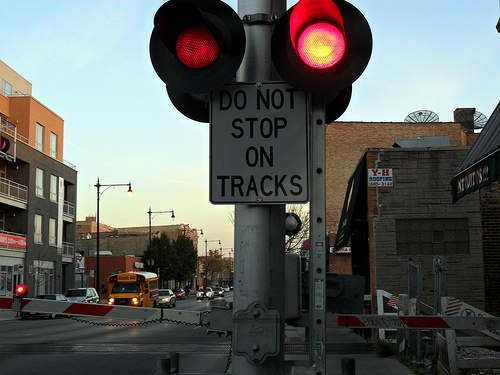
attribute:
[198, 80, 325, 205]
sign — white, black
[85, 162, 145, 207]
street light — on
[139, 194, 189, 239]
street light — on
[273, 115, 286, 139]
letter — black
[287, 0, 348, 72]
light — colored, red, on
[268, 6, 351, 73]
light — red, illuminated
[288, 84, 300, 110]
letter — black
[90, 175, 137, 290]
street lamp — tall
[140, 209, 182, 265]
street lamp — tall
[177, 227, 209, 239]
street lamp — tall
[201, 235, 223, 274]
street lamp — tall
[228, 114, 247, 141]
letter — Black 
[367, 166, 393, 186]
sign — white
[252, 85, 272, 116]
letter — Black 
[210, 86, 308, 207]
sign — traffic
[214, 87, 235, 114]
letter — black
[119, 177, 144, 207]
light — above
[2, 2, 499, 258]
sky — blue, white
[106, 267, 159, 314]
bus — school, waiting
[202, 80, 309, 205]
singboard — screwed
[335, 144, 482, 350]
buildings — old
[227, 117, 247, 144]
s — black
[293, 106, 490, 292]
building — old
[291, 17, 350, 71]
light — bright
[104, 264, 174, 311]
bus — school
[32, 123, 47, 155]
window — large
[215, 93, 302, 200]
letters — black